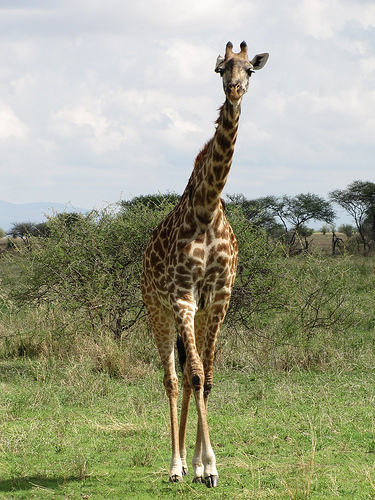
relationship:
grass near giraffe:
[3, 420, 123, 472] [133, 41, 307, 416]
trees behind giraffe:
[28, 232, 137, 322] [133, 41, 307, 416]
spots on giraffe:
[138, 260, 230, 284] [133, 41, 307, 416]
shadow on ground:
[0, 462, 75, 495] [58, 367, 138, 383]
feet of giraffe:
[193, 461, 216, 490] [133, 41, 307, 416]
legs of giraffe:
[126, 301, 229, 451] [133, 41, 307, 416]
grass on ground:
[3, 420, 123, 472] [58, 367, 138, 383]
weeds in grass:
[263, 312, 365, 370] [3, 420, 123, 472]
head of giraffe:
[208, 42, 271, 106] [133, 41, 307, 416]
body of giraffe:
[98, 206, 251, 318] [133, 41, 307, 416]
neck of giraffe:
[125, 108, 270, 214] [133, 41, 307, 416]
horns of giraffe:
[243, 38, 255, 61] [133, 41, 307, 416]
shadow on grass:
[0, 462, 75, 495] [3, 420, 123, 472]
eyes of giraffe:
[211, 57, 258, 78] [133, 41, 307, 416]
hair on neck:
[214, 115, 229, 129] [125, 108, 270, 214]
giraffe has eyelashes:
[133, 41, 307, 416] [249, 68, 259, 74]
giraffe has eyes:
[133, 41, 307, 416] [211, 57, 258, 78]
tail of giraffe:
[100, 296, 160, 345] [133, 41, 307, 416]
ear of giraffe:
[251, 51, 274, 80] [133, 41, 307, 416]